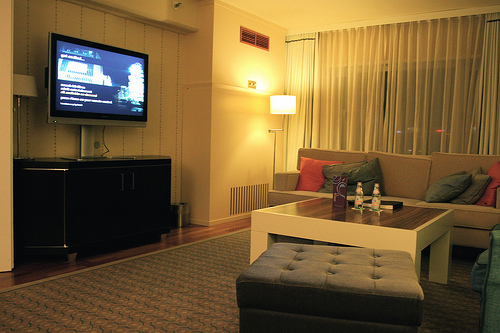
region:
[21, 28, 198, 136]
television on the wall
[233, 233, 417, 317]
soft surface on the ground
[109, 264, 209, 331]
ground next to the couch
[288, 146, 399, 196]
pillows on the couch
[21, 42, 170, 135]
television that is turned on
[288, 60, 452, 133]
curtains on the window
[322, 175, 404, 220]
items on the table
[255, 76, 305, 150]
light on the wall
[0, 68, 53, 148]
lamp not turned on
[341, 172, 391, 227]
two water bottles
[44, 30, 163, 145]
television hanging on the wall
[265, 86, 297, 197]
lamp in the corner of the room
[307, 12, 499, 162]
sheer curtains on the window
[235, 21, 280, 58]
vent on the top of the wall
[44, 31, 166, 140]
television is on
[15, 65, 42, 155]
lamp next to the television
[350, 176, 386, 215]
two bottles on the coffee table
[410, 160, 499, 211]
three pillows leaning like dominoes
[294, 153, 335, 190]
orange pillow on the couch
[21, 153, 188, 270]
black entertainment center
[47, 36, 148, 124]
A black and silver framed television.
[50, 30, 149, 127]
A flatscreen television.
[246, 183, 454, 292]
A coffee table.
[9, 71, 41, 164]
A table lamp.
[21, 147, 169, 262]
A black entertainment stand.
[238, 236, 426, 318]
A large square ottoman.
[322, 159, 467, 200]
Blue square throw pillows.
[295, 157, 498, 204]
Red small square pillows.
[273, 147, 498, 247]
A beige colored sofa.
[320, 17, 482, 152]
White sheer curtains.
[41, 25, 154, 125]
A flat screen tv on a black cabinet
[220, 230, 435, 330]
A grey/black foot rest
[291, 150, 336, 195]
A small pink pillow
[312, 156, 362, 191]
A small grey pillow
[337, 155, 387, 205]
A small blue pillow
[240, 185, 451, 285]
A white/wooden square table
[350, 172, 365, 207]
A bottled drink on a table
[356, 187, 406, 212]
A black book on a table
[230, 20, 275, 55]
A small red vent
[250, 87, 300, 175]
An odd looking floor lamp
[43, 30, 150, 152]
a tv on silver stand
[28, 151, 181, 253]
a black, glass topped cabinet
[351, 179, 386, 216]
a pair of bottled waters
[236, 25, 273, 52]
a red vent in the wall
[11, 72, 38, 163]
a tall desk lamp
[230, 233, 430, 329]
a dark colored ottoman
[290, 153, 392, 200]
an array of pillows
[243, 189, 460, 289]
white table with wood top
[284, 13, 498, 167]
some thin white curtains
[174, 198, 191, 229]
a small metal trashcan